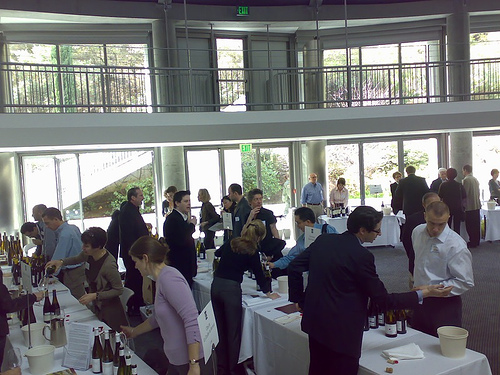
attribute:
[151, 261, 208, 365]
sweater —  lavender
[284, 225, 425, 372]
jacket — black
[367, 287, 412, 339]
bottles — wine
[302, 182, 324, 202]
shirt —  blue,  button down 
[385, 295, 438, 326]
bottles — wine's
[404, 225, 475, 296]
shirt — white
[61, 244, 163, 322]
sweater — brown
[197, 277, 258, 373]
pants — grey, woman's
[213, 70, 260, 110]
railing — gray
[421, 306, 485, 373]
buckets — white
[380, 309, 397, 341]
wine bottle —  of wine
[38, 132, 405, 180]
outside —  sunny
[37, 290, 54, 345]
bottle —  of wine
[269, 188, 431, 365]
suite — dark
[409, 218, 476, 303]
shirt — white, dress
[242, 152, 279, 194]
bush — green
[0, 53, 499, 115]
railing — grey, safety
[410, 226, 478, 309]
dress shirt —  white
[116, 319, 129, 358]
glass —  clear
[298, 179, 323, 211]
shirt —  blue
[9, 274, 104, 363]
pitcher — silver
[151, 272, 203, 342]
cardigan —  lilac 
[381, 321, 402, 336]
label —  white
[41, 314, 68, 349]
pitcher — metal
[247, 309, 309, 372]
tablecloth —  white